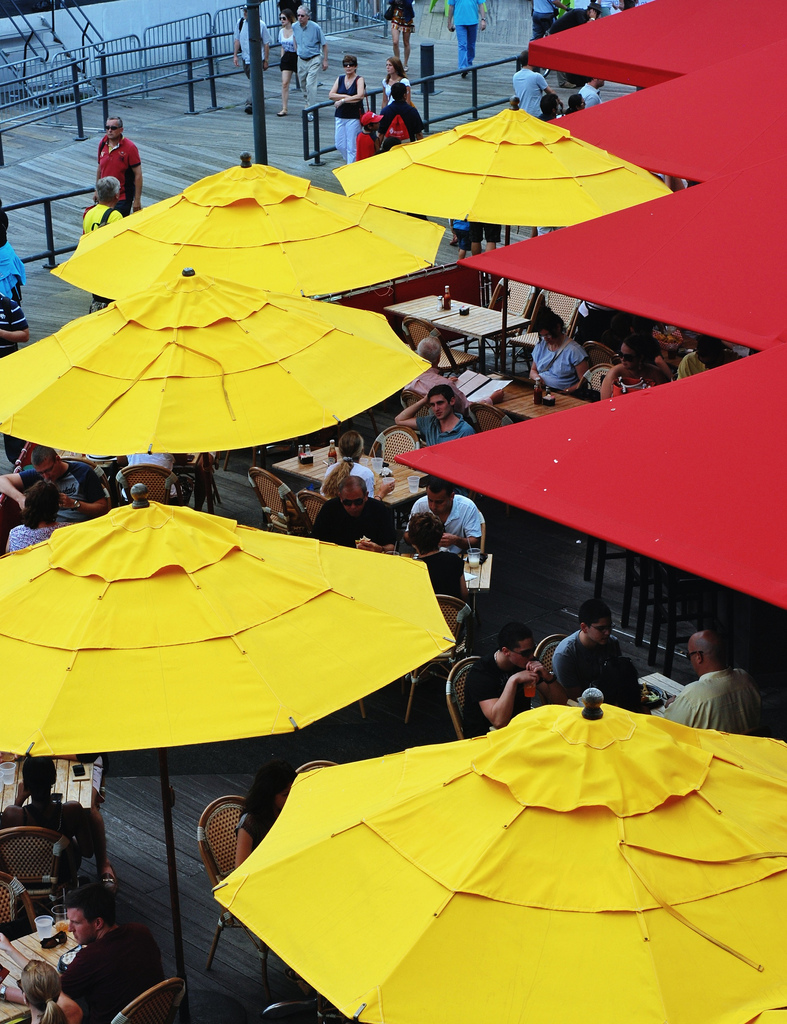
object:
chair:
[369, 425, 420, 471]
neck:
[494, 649, 510, 666]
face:
[341, 484, 364, 519]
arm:
[394, 394, 429, 430]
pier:
[0, 0, 531, 355]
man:
[96, 115, 143, 217]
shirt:
[96, 134, 141, 200]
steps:
[0, 0, 105, 107]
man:
[355, 110, 384, 160]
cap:
[360, 110, 384, 126]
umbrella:
[331, 96, 675, 228]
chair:
[533, 633, 573, 704]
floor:
[103, 748, 320, 1024]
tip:
[130, 482, 148, 499]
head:
[65, 882, 115, 943]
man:
[0, 882, 162, 1024]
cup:
[34, 915, 55, 939]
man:
[552, 599, 622, 705]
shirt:
[552, 629, 623, 705]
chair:
[105, 974, 187, 1024]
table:
[0, 918, 87, 1022]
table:
[317, 997, 348, 1021]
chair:
[264, 1000, 321, 1020]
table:
[0, 759, 94, 813]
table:
[272, 444, 429, 507]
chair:
[248, 466, 315, 535]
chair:
[488, 277, 535, 372]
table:
[384, 295, 532, 375]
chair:
[0, 824, 68, 925]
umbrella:
[207, 685, 787, 1024]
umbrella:
[0, 485, 457, 1024]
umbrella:
[392, 343, 786, 608]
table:
[638, 673, 686, 720]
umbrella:
[332, 95, 675, 379]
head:
[427, 384, 455, 419]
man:
[395, 384, 475, 447]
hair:
[427, 384, 454, 404]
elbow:
[394, 413, 409, 427]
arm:
[475, 670, 538, 728]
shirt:
[415, 406, 476, 445]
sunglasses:
[341, 495, 365, 508]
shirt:
[311, 496, 397, 548]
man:
[312, 476, 396, 555]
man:
[463, 621, 570, 738]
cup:
[524, 673, 537, 698]